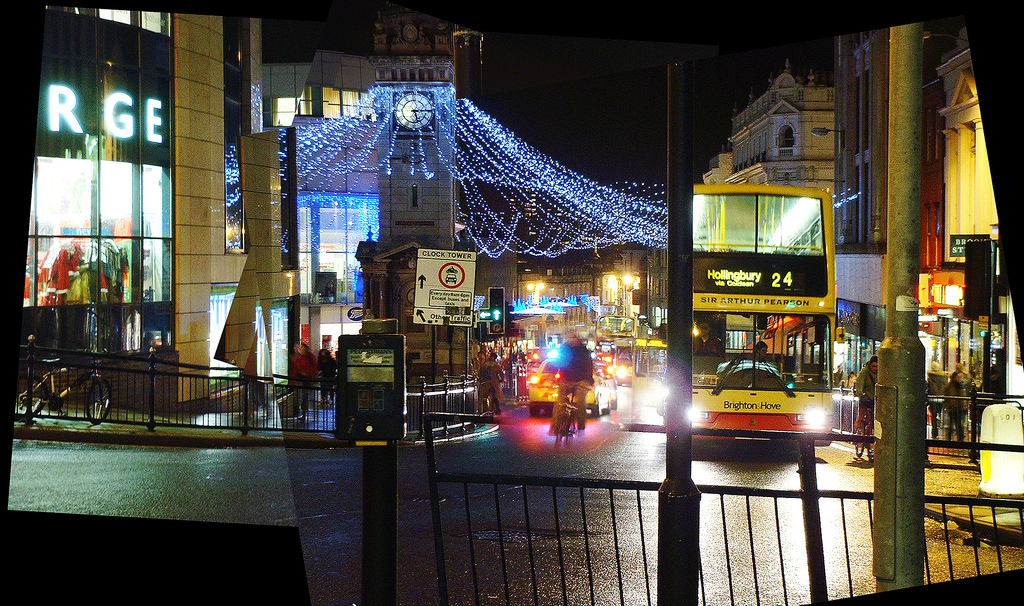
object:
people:
[472, 348, 524, 405]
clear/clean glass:
[692, 194, 824, 255]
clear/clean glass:
[29, 155, 172, 235]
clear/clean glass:
[25, 236, 172, 306]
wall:
[731, 115, 775, 184]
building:
[706, 58, 839, 184]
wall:
[378, 55, 459, 254]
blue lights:
[227, 80, 670, 256]